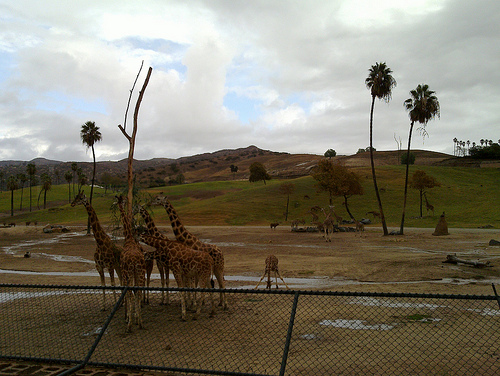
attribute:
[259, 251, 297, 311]
giraffe — young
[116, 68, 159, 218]
tree trunk — dead, tall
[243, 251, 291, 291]
unbalanced-baby giraffe — trying to drink water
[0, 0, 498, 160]
clouds — grey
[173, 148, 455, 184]
hill — brown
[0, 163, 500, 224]
hill — green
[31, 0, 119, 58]
giraffe — drinking, small 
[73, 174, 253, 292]
giraffe — five 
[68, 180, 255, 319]
giraffe — four